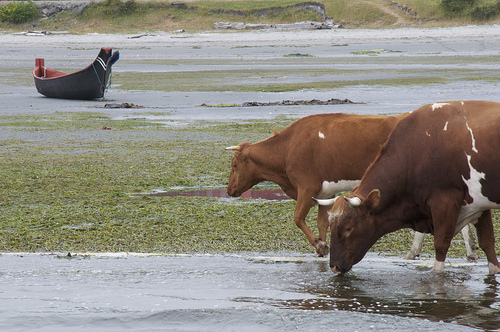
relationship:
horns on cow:
[317, 196, 367, 206] [218, 110, 380, 206]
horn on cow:
[226, 145, 240, 151] [313, 97, 499, 284]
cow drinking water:
[311, 99, 500, 275] [3, 35, 498, 327]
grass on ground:
[0, 113, 499, 252] [0, 0, 500, 331]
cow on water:
[300, 103, 497, 295] [3, 247, 497, 329]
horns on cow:
[312, 196, 362, 208] [170, 57, 498, 310]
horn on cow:
[215, 142, 246, 155] [224, 110, 474, 262]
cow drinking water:
[311, 99, 500, 275] [3, 247, 497, 329]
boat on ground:
[31, 44, 119, 101] [0, 30, 499, 256]